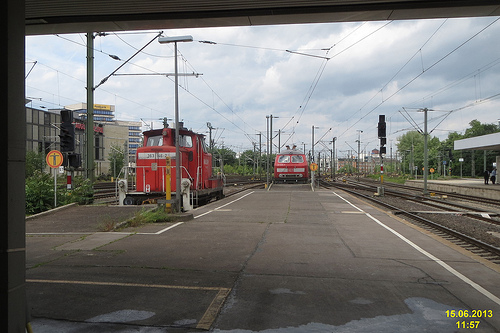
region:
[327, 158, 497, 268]
Train tracks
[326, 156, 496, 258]
A set of train tracks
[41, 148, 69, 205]
A sign for the train tracks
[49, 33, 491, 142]
Wires for the trains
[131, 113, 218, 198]
A red train car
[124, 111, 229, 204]
Parked train car on tracks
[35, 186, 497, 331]
Sidewalk next to train tracks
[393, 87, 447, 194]
Pole holding wire for trains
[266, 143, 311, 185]
A parked train on tracks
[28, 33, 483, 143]
Cloudy sky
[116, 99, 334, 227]
vehicles on the road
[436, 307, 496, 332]
timestamp on the right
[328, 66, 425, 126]
sky is mostly cloudy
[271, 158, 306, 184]
the vehicle is red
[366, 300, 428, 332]
water on the road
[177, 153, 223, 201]
the vehicle is red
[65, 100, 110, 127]
building in the back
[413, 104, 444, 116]
top of the powerline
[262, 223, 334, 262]
the ground is asphalt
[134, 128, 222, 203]
the train sitting at the end of the track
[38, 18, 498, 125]
the white clouds sitting in the sky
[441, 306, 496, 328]
the time stamp sitting in the corner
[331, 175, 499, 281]
the empty tracks off to the side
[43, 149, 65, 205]
a sign sitting on the pole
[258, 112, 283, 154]
some poles sitting by the train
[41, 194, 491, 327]
a parking lot for cars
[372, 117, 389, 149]
some lights sitting on the pole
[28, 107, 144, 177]
some buildings off to the side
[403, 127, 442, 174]
a green leafy tree off to the side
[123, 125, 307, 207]
two red train engine at the end of the tracks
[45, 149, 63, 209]
red, yellow, and black sign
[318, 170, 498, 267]
sets of rail road tracks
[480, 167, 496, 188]
people standing on the platform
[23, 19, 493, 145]
power lines running above the trains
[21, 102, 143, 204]
buildings next to the train tracks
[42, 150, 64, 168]
circular warning sign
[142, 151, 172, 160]
model number on the front of the train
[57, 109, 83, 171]
stop lights on a pole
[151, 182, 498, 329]
white lines on the edges of the plateform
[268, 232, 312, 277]
the street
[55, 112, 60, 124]
tan window on the building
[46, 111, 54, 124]
tan window on the building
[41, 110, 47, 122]
tan window on the building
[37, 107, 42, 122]
tan window on the building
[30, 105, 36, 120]
tan window on the building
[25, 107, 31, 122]
tan window on the building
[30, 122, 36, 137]
tan window on the building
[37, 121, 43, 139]
tan window on the building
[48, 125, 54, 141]
tan window on the building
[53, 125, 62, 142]
tan window on the building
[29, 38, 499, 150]
cloud covered sky above the train tracks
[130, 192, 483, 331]
white lines painted on the pavement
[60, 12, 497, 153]
power lines above the pavement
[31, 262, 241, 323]
yellow lines painted on the pavement